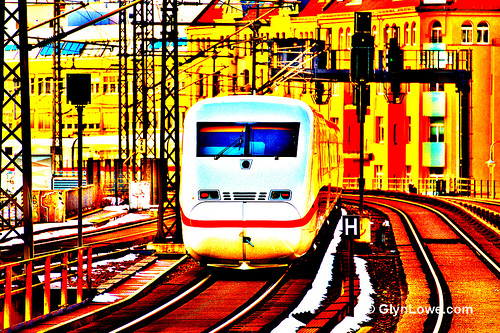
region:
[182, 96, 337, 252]
train on the track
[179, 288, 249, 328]
track train is on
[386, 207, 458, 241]
track for the train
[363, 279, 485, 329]
credit to artist for image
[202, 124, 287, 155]
windows on the train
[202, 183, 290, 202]
lights on the train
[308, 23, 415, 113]
lights on the track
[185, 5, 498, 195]
buildings next to track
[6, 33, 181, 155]
building behind the train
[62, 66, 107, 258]
pole near the track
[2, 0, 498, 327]
the picture of a train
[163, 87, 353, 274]
train is white and yellow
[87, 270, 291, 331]
the rails of train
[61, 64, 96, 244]
a black sign on side a railroad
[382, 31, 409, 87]
a traffic light in green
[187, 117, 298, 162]
black wipes on window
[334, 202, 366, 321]
a sign with letter H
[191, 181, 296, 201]
red lights on front train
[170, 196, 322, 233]
a red stripe on front train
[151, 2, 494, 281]
a building behind a train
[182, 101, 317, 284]
the train is white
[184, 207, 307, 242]
the line is red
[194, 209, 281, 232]
the line is red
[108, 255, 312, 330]
white and black tracks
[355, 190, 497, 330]
white and black tracks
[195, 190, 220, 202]
red lights on train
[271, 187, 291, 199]
red light on train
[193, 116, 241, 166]
blue windows on train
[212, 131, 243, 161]
black wiper on window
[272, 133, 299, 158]
black wiper on window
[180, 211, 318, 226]
red trim on train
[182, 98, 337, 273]
white train on tracks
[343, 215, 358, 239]
white h on black sign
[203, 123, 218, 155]
window of a train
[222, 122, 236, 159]
window of a train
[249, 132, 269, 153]
window of a train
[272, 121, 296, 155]
window of a train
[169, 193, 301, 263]
front of a train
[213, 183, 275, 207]
grill of a train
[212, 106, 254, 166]
wiper of a train